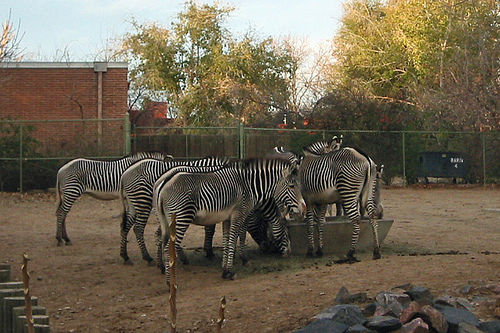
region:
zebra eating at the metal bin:
[45, 145, 174, 245]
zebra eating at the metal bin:
[113, 152, 230, 269]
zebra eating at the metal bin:
[148, 155, 308, 285]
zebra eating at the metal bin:
[294, 134, 389, 266]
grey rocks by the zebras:
[292, 285, 488, 331]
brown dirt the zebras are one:
[1, 187, 495, 327]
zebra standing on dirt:
[155, 150, 307, 289]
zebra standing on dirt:
[152, 165, 289, 276]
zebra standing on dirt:
[116, 155, 234, 270]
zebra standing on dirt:
[51, 152, 174, 248]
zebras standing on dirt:
[48, 128, 390, 268]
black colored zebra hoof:
[226, 273, 238, 279]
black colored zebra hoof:
[304, 250, 314, 259]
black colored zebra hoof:
[315, 246, 325, 256]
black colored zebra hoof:
[345, 250, 357, 258]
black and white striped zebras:
[52, 141, 419, 281]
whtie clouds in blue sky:
[41, 9, 92, 51]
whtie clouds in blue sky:
[247, 5, 289, 36]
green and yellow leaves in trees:
[422, 61, 474, 96]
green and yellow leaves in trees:
[424, 82, 486, 126]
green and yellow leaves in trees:
[445, 9, 480, 36]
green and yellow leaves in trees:
[401, 12, 469, 44]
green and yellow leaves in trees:
[148, 21, 218, 73]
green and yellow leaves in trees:
[185, 53, 246, 91]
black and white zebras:
[118, 127, 306, 257]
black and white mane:
[236, 153, 286, 183]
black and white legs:
[176, 187, 236, 259]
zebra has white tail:
[138, 181, 184, 262]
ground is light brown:
[413, 192, 481, 257]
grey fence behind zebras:
[136, 123, 408, 155]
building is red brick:
[2, 58, 118, 161]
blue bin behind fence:
[408, 144, 495, 204]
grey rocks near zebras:
[331, 252, 489, 332]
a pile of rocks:
[306, 280, 469, 325]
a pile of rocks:
[307, 265, 454, 325]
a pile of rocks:
[294, 270, 409, 320]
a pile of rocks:
[277, 268, 434, 325]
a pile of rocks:
[280, 268, 482, 329]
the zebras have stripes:
[35, 133, 409, 290]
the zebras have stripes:
[40, 135, 388, 283]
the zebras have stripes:
[32, 111, 407, 291]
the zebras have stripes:
[40, 120, 412, 307]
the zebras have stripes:
[37, 125, 397, 277]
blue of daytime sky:
[4, 2, 344, 115]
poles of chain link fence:
[3, 115, 496, 189]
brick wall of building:
[5, 60, 128, 186]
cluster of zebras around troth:
[51, 135, 391, 275]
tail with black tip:
[117, 180, 129, 235]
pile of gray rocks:
[306, 285, 484, 331]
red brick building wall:
[0, 67, 127, 185]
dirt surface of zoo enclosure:
[1, 187, 496, 330]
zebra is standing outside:
[156, 156, 307, 278]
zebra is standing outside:
[152, 165, 291, 264]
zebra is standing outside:
[119, 156, 234, 265]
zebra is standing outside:
[55, 152, 173, 242]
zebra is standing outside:
[300, 137, 382, 262]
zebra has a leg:
[228, 206, 246, 284]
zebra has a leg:
[173, 211, 190, 264]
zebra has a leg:
[129, 196, 153, 264]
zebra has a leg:
[118, 205, 137, 265]